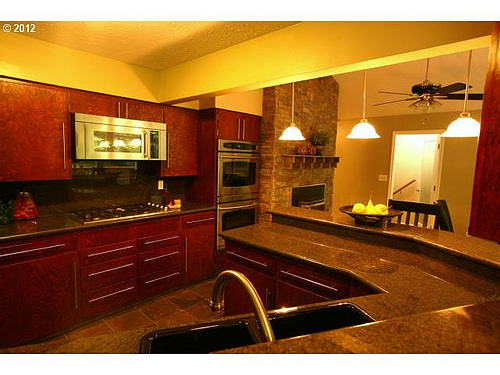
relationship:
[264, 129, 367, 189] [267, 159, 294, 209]
shelf on wall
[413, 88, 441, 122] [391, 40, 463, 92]
light on fan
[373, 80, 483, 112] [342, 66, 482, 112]
fan on ceiling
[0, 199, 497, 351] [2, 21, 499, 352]
countertops in kitchen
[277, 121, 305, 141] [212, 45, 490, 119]
light on ceiling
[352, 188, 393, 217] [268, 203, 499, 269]
fruit on counter